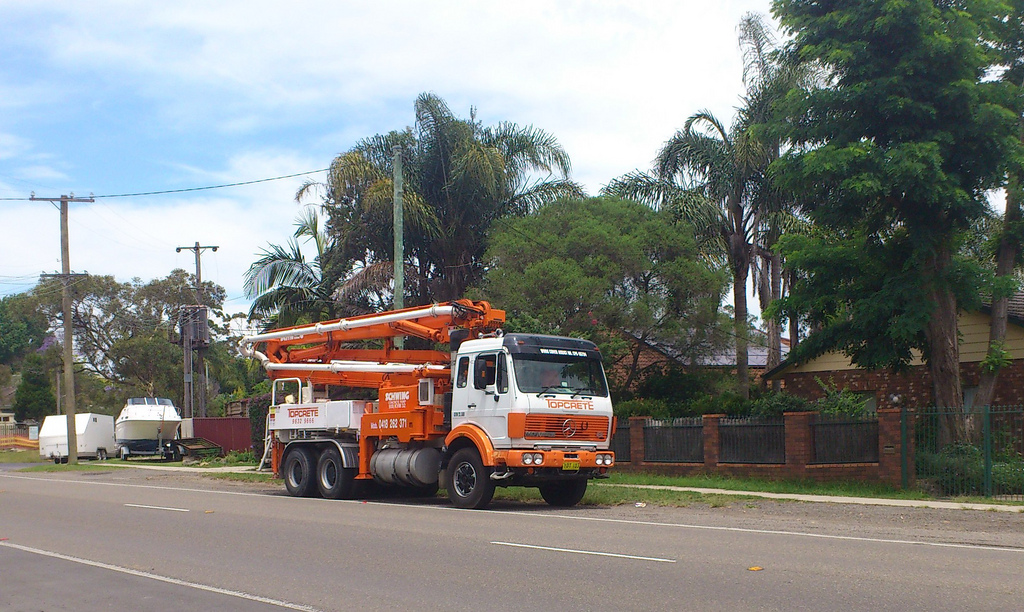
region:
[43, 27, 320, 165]
its a sunny cloudy day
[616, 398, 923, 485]
brick and iron fence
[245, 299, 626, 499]
large orange and white truck with crane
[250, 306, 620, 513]
a white and orange utility truck parked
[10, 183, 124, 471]
a telephone pole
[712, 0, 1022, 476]
a very large tree with green leaves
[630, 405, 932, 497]
a brick and iron fence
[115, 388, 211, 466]
a white boat parked in a driveway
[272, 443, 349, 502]
a set of two rear truck tires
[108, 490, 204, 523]
the white middle line in the street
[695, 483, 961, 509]
a section of the sidewalk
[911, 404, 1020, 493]
a green iron fence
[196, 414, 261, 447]
a red fence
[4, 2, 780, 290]
blue sky with clouds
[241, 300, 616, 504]
orange and white utility vehicle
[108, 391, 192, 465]
boat parked on a hauling trailer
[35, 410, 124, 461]
camper trailer parked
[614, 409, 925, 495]
brick and metal fencing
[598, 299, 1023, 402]
brick and wood homes behind a fence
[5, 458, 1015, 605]
road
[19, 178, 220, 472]
several utility poles with lines attached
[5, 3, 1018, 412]
various trees along street and in background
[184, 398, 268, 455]
red painted fencing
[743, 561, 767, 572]
an orange reflector on the road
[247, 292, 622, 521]
orange vehicle by the road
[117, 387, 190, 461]
white boat on side of road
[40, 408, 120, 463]
white trailer near boat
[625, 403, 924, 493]
brick and rail fence in front of house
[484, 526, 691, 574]
white line on road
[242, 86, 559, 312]
palm trees behind vehicle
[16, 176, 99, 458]
large pole in front of trailer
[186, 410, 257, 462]
red fence behind vehicle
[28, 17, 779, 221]
blue, partially clouded sky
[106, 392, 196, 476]
WHITE BOAT ON A TRAILOR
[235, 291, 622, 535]
UTILITY TRUCK PARKED ON THE SIDE OF THE STREET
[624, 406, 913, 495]
A BRICK AND IRON FENCE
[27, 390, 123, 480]
A CAMPER PARKED BESIDE THE STREET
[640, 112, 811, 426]
PALM TREE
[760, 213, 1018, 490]
HOUSE SHADED BY LARGE TREES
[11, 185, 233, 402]
POWER LINES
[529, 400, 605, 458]
MERCEDES SYMBOL ON UTILITY TRUCK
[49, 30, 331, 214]
A PARTLY CLOUDY SKY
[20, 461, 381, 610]
A STREET WITHOUT A LOT OF TRAFFIC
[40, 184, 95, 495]
tall electrical/telephone pole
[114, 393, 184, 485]
white boat on a trailer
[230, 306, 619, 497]
orange and white cement pumping truck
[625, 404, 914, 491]
red and black brick and iron fence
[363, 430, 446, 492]
extra large gas tank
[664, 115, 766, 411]
tall skinny palm tree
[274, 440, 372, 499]
two sets of dual tires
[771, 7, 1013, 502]
large tree in front of house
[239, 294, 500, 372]
boom arm for pumping cement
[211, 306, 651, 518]
big truck parked on side of road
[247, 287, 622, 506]
an orange and white truck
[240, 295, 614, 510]
an orange and white utility truck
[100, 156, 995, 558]
the truck is on the street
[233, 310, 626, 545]
Orange and white crane truck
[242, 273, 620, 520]
a large orange vehicle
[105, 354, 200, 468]
a large white boat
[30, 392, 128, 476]
a small white camper trailer